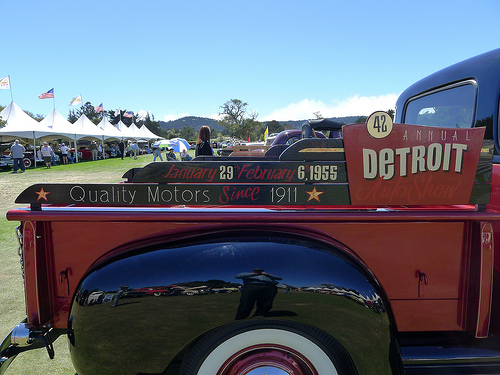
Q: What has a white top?
A: Tents.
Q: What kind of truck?
A: Antique.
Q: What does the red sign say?
A: Detroit.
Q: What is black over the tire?
A: Fender.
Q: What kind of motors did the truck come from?
A: Quality.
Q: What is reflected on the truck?
A: Male.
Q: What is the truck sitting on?
A: Grass.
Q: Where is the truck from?
A: Detroit.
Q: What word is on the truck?
A: Detroit.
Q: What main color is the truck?
A: Red.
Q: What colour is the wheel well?
A: Black.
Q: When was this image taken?
A: During the day.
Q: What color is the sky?
A: Blue.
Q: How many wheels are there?
A: One.